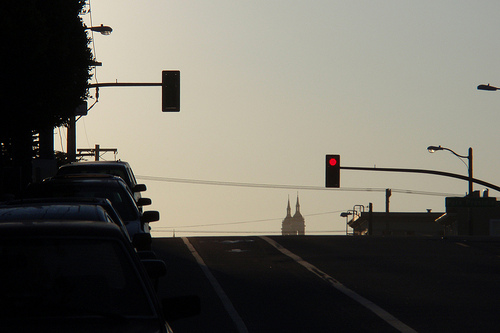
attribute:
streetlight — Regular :
[428, 142, 475, 200]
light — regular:
[93, 20, 130, 49]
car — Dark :
[2, 198, 152, 326]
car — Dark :
[52, 172, 131, 208]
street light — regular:
[324, 152, 344, 188]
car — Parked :
[8, 163, 191, 257]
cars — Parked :
[14, 142, 189, 331]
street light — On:
[160, 68, 182, 113]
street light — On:
[325, 154, 347, 192]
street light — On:
[422, 141, 441, 153]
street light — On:
[472, 78, 497, 93]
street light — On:
[87, 16, 115, 38]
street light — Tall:
[320, 149, 498, 205]